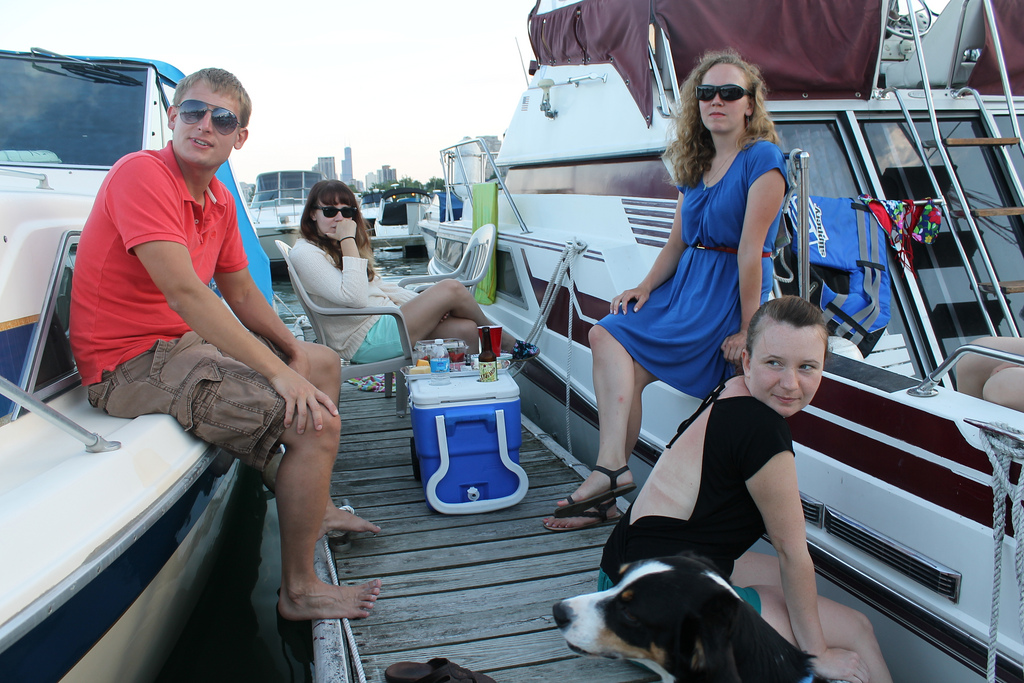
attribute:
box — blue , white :
[402, 356, 534, 517]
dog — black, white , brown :
[545, 549, 827, 679]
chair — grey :
[262, 231, 422, 460]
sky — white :
[324, 39, 428, 117]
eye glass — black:
[692, 84, 757, 104]